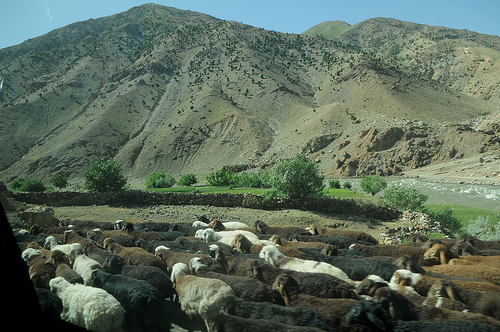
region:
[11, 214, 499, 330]
a herd of sheep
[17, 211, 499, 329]
a bunch of sheep crowded together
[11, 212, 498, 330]
different colored sheep herded together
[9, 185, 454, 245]
a row of rocks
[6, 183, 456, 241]
a rocky ledge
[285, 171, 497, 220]
a small river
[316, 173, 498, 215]
a river in the background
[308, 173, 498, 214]
a river with small rapids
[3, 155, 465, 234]
a row of green shrubs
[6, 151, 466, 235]
a row of green trees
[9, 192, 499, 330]
a herd of animals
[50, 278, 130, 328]
fluffy white sheep walking in the herd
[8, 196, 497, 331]
black, brown, and white sheep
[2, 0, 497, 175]
brown and black mountain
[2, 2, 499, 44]
bright blue sky with no visible clouds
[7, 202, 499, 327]
sheep walking in a group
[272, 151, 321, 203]
small dark green bush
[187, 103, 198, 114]
small black dot on the mountain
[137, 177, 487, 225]
thin strip of green grass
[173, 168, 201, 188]
small green bush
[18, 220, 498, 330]
The sheep are black, white, and brown.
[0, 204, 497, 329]
The sheep are facing left.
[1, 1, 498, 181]
The mountains are brown.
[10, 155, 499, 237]
The trees and bushes are green.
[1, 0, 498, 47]
The sky is blue.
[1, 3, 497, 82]
The tops of the mountains have trees and bushes.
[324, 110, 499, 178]
The terrain is rocky.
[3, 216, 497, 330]
The sheep are moving.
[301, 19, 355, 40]
The mountain has green in it.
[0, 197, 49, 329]
The corner is dark and obscured.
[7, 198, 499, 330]
these are sheep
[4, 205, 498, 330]
a large group of sheep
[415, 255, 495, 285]
this is a brown sheep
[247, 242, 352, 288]
this is a white sheep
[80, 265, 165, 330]
this is a black sheep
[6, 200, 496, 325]
this is a herd of sheep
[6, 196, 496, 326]
these sheep are fluffy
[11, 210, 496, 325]
these sheep are wooly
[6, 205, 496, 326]
these sheep have a lot of wool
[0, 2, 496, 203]
the mountain is tall with small green trees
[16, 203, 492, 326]
A large number of sheep walking through a valley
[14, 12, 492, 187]
A large mountain in the distance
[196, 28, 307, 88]
Trees litter the surface of the mountain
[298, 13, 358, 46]
Grass growing on the peak of a large mountain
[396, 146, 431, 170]
A rocky outcropping on the hill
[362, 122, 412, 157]
A very large boulder on the side of the hill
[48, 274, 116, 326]
An unsheared white sheep walking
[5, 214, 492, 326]
Brown, grey, and black sheep walking together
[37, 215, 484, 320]
None of the sheep are grazing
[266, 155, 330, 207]
Healthy green trees behind the sheep